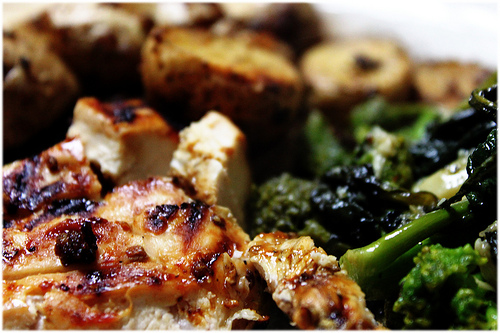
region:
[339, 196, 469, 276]
green cooked vegetable stem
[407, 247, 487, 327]
piece of cooked broccoli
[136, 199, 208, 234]
char marks on piece of food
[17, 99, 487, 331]
cooked food dish on plate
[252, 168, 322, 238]
top of cooked broccoli piece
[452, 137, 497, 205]
cooked green vegetable piece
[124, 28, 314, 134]
piece of cooked bread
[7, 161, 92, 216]
piece of cooked food with char marks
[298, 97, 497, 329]
pile of cooked green vegetables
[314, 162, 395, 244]
dark green cooked vegetable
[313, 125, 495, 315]
broccoli on a plate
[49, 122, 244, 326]
chicken on a plate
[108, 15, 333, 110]
potatoes on a plate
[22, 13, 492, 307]
food on a plate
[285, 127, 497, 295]
Green leafy vegetable on the plate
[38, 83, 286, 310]
chicken on the plate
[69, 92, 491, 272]
chicken and vegetable on a plate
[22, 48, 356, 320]
this is a piece of meat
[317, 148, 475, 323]
this is a veggie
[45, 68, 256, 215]
this is a cut piece of meat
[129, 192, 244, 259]
black portion on meat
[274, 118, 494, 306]
veggies have been cooked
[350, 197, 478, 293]
stem on a vegetables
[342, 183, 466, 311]
the stem is green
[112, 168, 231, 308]
the meat is golden brown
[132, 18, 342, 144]
the potatoes are cut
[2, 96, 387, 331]
chopped grilled chicken breast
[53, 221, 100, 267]
a charred piece of chicken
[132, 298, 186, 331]
the white meat interior of a piece of chicken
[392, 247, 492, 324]
a green floret of broccoli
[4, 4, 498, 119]
roasted baby potatoes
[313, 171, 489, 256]
charred and wilted spinach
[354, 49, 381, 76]
a charred chunk on top of a potato slice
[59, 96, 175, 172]
a chunk of grilled chicken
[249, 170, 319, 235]
a dark green brussels sprout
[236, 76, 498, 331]
green roasted cruciferous vegetables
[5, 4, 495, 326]
a mouth-watering meal ready to be eaten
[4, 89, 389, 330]
charbroiled chunks of chicken in this meal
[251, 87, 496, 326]
steamed vegetables are part of this dish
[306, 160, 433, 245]
this dark green stuff looks like spinach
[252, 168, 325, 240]
this looks like a broccoli floret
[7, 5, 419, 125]
chunks of potatoes in this dish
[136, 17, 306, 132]
potatoes have been nicely browned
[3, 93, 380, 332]
chicken breast is a very healthy food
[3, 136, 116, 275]
dark spots indicate the chicken has been broiled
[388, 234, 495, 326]
another broccoli floret